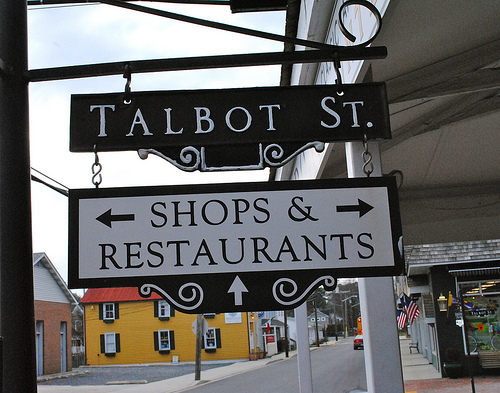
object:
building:
[85, 286, 262, 365]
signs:
[68, 183, 408, 315]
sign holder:
[0, 0, 404, 393]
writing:
[90, 104, 280, 138]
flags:
[399, 292, 421, 325]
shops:
[435, 267, 500, 377]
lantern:
[437, 293, 448, 312]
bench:
[409, 339, 420, 355]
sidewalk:
[399, 333, 441, 380]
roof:
[79, 284, 163, 301]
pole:
[344, 142, 403, 392]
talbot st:
[90, 97, 362, 138]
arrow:
[94, 208, 135, 228]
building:
[33, 253, 82, 379]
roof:
[32, 252, 79, 303]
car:
[354, 335, 365, 350]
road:
[186, 338, 364, 392]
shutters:
[100, 334, 106, 353]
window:
[104, 334, 116, 353]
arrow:
[227, 276, 249, 306]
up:
[227, 273, 248, 305]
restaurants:
[97, 232, 374, 269]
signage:
[70, 84, 389, 171]